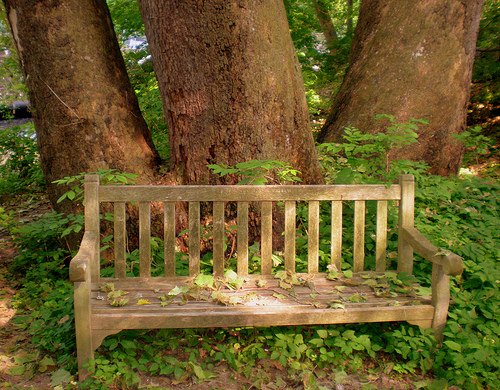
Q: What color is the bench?
A: Brown.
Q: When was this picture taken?
A: Daytime.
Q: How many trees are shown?
A: Three.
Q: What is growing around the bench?
A: Ivy.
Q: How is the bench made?
A: With wood.